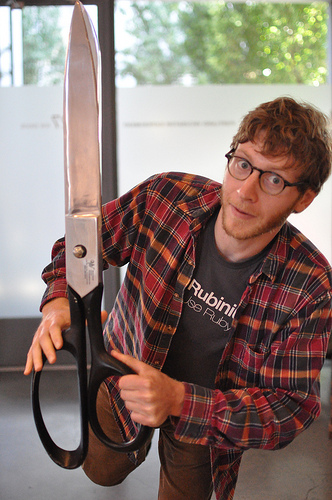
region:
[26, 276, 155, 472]
the handle is black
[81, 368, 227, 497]
the pants are brown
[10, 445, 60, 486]
the floor is gray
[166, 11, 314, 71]
the trees are green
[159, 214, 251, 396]
the shirt is black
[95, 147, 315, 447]
the shirt is red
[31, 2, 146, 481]
the scissors are big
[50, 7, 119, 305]
the scissor is gray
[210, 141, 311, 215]
the glasses are black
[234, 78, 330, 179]
the hair is blond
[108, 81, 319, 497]
A man with red hair.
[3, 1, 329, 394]
Man holding a pair of over-sized scissors.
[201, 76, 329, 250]
A man with black eyeglasses.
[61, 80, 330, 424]
Man wearing a red, brown and orange flannel shirt.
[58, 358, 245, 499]
Man wearing a pair of brown pants.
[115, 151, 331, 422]
A man wearing a black t-shirt.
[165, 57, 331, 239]
A young man with red hair.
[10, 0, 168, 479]
A pair of enormously over-sized scissors.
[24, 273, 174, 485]
Black handles on a pair of scissors.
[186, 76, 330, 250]
Young man with a red beard.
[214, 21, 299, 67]
the leaves are green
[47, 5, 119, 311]
the blade is silver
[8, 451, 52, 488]
the floor is white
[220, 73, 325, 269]
the man is white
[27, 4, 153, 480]
Giant scissors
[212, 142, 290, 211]
Glasses on man's face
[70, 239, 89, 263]
Screw holding giant scissors together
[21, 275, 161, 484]
Black handle on giant scissors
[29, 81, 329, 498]
Man holding giant scissors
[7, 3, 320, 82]
Windows in background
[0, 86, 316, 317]
White wall in background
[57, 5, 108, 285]
Silver blades of giant scissors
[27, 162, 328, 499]
Plaid shirt worn by man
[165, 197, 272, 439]
Black t-shirt worn by man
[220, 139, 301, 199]
The man is wearing glasses.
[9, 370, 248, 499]
The man is kneeling on the floor.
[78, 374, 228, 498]
The man is wearing brown pants.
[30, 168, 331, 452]
The man is wearing a checkered shirt.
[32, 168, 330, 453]
Checkered shirt has long sleeves.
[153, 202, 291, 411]
Black tee shirt beneath flannel shirt.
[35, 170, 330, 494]
Checkered shirt is flannel.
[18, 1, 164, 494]
Man is holding large pair of scissors.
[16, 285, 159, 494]
The scissors have black handles.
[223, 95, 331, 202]
The man has red hair.